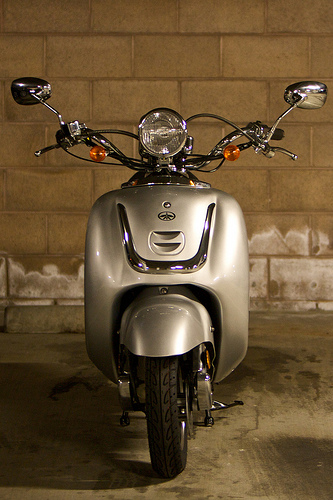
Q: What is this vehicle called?
A: Motor scooter.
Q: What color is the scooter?
A: Gray.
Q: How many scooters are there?
A: One.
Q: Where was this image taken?
A: Parking lot.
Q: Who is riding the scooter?
A: No one.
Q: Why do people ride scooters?
A: Transportation.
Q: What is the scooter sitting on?
A: Concrete.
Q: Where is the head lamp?
A: Between the handlebars.